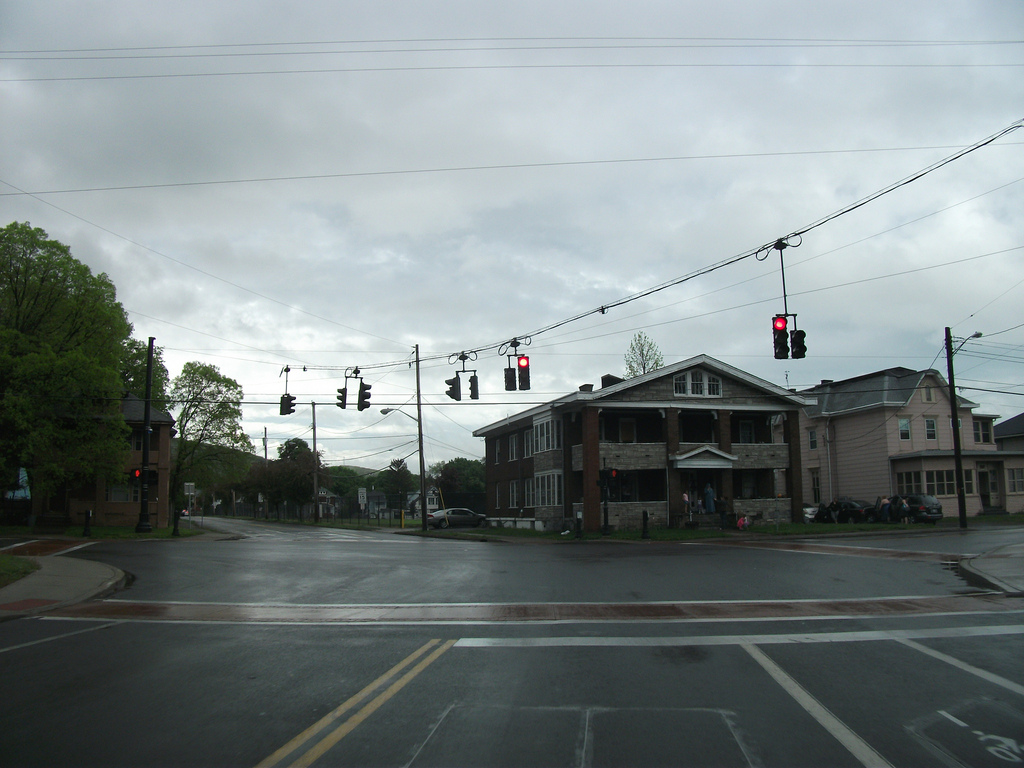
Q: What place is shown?
A: It is a street.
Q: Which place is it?
A: It is a street.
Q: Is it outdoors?
A: Yes, it is outdoors.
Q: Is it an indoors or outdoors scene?
A: It is outdoors.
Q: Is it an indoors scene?
A: No, it is outdoors.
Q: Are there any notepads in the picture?
A: No, there are no notepads.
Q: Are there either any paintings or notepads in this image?
A: No, there are no notepads or paintings.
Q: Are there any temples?
A: No, there are no temples.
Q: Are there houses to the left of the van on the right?
A: Yes, there is a house to the left of the van.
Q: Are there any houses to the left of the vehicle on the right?
A: Yes, there is a house to the left of the van.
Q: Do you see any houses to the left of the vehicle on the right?
A: Yes, there is a house to the left of the van.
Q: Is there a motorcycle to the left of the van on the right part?
A: No, there is a house to the left of the van.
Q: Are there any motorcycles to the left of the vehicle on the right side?
A: No, there is a house to the left of the van.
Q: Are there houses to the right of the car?
A: Yes, there is a house to the right of the car.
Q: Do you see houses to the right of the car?
A: Yes, there is a house to the right of the car.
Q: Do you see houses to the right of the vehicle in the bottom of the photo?
A: Yes, there is a house to the right of the car.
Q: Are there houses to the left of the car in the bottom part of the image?
A: No, the house is to the right of the car.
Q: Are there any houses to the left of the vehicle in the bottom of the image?
A: No, the house is to the right of the car.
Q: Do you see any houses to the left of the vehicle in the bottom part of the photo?
A: No, the house is to the right of the car.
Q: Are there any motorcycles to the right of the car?
A: No, there is a house to the right of the car.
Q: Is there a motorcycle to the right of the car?
A: No, there is a house to the right of the car.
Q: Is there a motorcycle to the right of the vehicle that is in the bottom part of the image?
A: No, there is a house to the right of the car.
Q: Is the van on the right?
A: Yes, the van is on the right of the image.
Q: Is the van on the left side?
A: No, the van is on the right of the image.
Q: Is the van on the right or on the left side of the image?
A: The van is on the right of the image.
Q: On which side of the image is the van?
A: The van is on the right of the image.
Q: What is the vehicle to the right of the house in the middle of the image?
A: The vehicle is a van.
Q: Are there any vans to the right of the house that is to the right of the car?
A: Yes, there is a van to the right of the house.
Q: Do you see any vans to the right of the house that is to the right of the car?
A: Yes, there is a van to the right of the house.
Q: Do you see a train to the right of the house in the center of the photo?
A: No, there is a van to the right of the house.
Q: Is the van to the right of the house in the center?
A: Yes, the van is to the right of the house.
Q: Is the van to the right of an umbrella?
A: No, the van is to the right of the house.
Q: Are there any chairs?
A: No, there are no chairs.